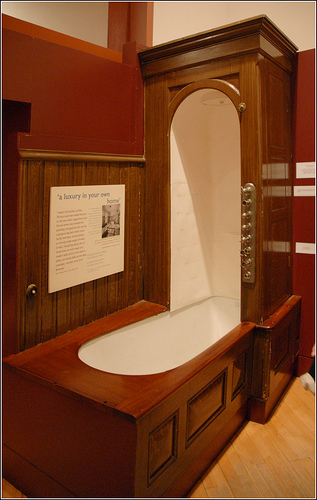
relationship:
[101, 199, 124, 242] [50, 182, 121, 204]
picture beneath words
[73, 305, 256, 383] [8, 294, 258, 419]
bathtub has wood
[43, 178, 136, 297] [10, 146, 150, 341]
sign on wall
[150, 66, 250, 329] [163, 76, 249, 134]
shower has arch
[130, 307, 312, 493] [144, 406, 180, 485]
wood has panels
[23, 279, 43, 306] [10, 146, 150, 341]
knob on wall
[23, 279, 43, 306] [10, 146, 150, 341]
knob on a wall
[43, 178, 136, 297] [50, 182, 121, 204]
sign has words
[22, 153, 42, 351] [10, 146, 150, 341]
panel on wall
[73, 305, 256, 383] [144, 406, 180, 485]
bathtub has panels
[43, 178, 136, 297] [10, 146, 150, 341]
sign hung on wall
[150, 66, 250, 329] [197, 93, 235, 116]
shower has circle